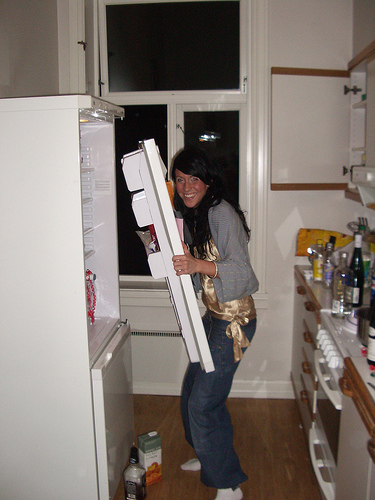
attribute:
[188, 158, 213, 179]
hair — black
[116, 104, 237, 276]
window — glass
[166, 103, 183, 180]
panel — white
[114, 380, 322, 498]
floor — brown, wood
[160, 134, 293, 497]
woman — happy, smiling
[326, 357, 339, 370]
knob — white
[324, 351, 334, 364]
knob — white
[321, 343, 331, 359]
knob — white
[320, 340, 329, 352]
knob — white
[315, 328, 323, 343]
knob — white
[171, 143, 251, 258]
hair — dark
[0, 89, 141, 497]
refrigerator — white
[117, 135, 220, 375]
door — of freezer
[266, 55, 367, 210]
door — open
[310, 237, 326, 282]
bottle — colorless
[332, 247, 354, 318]
vodka bottle — absolute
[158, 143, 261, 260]
hair — long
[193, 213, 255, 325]
shirt — gold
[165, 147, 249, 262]
hair — long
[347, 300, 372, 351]
pot — silver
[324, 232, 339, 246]
top — black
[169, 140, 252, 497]
woman — smling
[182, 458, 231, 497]
socks — white